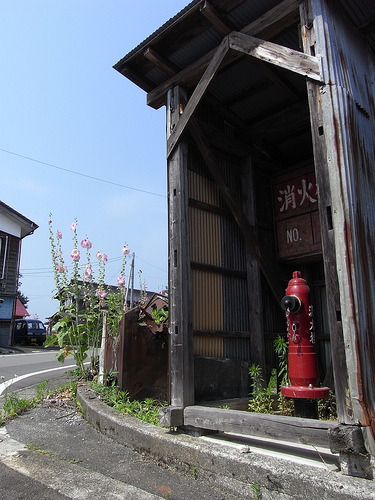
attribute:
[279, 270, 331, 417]
fire hydrant — red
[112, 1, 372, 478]
building — wooden, old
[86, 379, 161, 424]
grass — green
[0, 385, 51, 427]
grass — green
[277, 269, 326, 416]
hydrant — red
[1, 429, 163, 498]
line — white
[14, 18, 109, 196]
sky — clear, blue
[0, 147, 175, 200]
power line — single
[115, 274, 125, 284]
flower — tall, pink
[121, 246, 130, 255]
flower — tall, pink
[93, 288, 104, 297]
flower — tall, pink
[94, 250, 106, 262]
flower — tall, pink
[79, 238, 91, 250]
flower — tall, pink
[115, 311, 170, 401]
fence — rusty, brown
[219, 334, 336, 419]
weeds — small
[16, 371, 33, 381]
paint — white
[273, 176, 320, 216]
letters — white, Chinese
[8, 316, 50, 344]
car — blue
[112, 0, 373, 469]
wooden shack — small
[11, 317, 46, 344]
car — blue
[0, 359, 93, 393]
line — white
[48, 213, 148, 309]
flowers — Purple